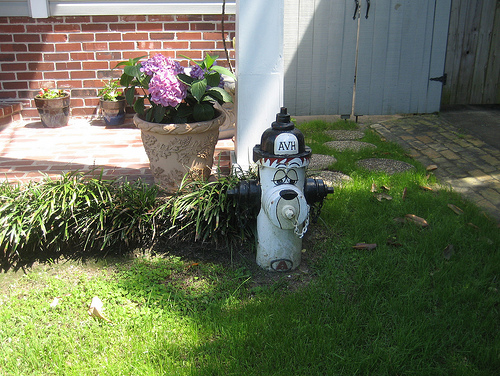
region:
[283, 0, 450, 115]
white painted wooden gate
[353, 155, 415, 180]
round paving stone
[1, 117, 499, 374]
patch of short green grass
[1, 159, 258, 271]
section of long tufted grass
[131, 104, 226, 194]
beige decorative pot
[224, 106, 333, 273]
black and white painted fire hydrant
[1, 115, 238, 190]
red brick patio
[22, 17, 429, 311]
this is a front yard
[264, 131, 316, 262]
this is a hydrant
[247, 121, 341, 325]
the hydrant is white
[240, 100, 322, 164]
the top of the hydrant is black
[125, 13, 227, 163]
the plant is potted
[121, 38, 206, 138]
the plant is flowers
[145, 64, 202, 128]
the flowers are pink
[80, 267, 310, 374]
the lawn is mowed and green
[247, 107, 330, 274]
a painted fire hydrant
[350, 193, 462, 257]
brown leaves on the ground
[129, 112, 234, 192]
a large tan flower pot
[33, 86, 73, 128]
a brown flower pot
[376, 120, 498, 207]
a brick walk way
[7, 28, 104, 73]
a red brick wall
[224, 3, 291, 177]
a white wood post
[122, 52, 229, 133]
a pink and purple plant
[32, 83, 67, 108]
a red and green plant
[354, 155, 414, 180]
round stepping stone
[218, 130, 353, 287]
white hydrant on grass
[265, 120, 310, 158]
hydrant has black cap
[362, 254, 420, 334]
grass is bright green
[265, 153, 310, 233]
Dog face painted on a fire hydrant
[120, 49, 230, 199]
Flowers in a large planter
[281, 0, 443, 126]
White wooden doors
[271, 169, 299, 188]
Two eyes on the fire hydrant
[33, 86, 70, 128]
Plants in a pot on the patio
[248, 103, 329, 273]
FIre hydrant in the grass painted like a dog.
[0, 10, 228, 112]
Side of a brick wall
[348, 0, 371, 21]
Black handles on the door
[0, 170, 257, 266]
Green plants in the grass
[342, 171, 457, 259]
Leaves on the ground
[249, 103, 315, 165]
top of fire hydrant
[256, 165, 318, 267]
bottom of fire hydrant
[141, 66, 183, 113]
pink flower of pot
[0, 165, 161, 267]
bush to the left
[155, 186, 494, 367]
shadow in grass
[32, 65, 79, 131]
left rear pot on patio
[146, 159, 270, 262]
right bush behind hydrant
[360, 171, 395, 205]
three dead leaves on grass together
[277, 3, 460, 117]
white double door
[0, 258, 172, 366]
part of grass not in shadow